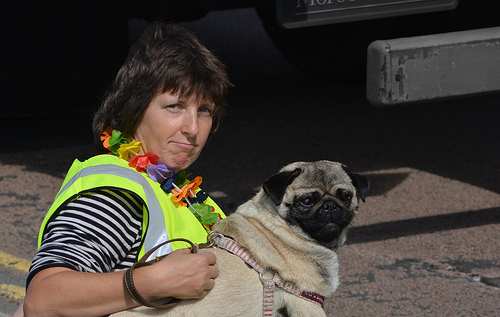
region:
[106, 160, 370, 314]
brown pug with black ears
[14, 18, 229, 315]
woman holding a small dog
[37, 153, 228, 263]
bright yellow vest on the woman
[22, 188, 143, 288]
black and white stripped shirt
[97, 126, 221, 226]
necklace with several color flowers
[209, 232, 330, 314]
red and white harness on the dog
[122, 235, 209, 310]
brown yellow leash in the woman's hand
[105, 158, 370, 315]
pug with a red and white leash on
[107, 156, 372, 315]
small dog on a leash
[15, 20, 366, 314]
woman sitting with her dog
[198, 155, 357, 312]
tan and black pug dog with a harness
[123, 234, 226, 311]
woman's hand holding a leash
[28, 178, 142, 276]
black and white striped sleeve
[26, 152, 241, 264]
yellow and silver safety reflecting vest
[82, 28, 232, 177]
woman's head with dark brown hair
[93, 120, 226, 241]
orange, green, yellow, red, purple and blue lei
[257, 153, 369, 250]
head of black and tan pug dog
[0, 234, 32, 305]
chipped yellow painted lines on pavement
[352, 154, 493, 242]
dark shadows on cement pavement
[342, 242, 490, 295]
dark stains on cement pavement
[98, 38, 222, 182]
the woman is looking head on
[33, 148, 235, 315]
the woman is wearing a vest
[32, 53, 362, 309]
the woman is with a dog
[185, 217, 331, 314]
the dog has a harness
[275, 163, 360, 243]
the dog is looking at the camera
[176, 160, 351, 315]
the dog is light brown in color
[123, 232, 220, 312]
the woman is holding the dog leash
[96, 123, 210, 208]
the woman is wearing a flower collar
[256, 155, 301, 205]
the dog has black ears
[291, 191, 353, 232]
the dog has a black snout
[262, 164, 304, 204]
the dog's right ear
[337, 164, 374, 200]
the dog's left ear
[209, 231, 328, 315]
the dog's red and white harness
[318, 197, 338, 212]
the dog's black nose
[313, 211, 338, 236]
the dog's mouth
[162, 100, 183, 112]
the woman's right eye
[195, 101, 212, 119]
the woman's left eye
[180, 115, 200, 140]
the woman's nose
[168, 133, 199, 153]
the woman's closed mouth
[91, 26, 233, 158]
the woman's black hair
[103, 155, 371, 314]
a fat pug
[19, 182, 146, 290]
a black striped shirt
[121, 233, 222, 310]
leather leash in her hand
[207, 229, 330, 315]
white and pink harness on the dog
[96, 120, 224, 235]
flowered lei around her neck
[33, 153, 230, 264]
a yellow safety vest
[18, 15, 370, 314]
a woman holding a pug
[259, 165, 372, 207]
black ears on the dog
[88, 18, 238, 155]
a brown mullet haircut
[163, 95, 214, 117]
blue eyes